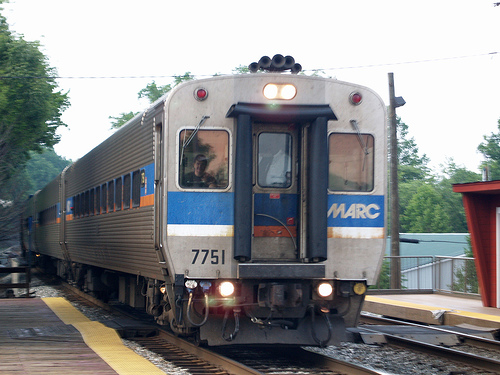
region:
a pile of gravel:
[348, 346, 420, 371]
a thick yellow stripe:
[43, 290, 148, 373]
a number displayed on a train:
[186, 245, 231, 271]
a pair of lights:
[260, 79, 305, 104]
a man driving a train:
[177, 153, 224, 193]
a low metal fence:
[385, 251, 484, 299]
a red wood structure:
[448, 170, 498, 310]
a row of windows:
[58, 178, 148, 215]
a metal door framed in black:
[233, 99, 338, 266]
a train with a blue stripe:
[1, 64, 401, 339]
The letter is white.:
[327, 198, 347, 223]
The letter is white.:
[342, 199, 357, 227]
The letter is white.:
[352, 199, 367, 221]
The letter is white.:
[364, 198, 384, 223]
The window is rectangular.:
[325, 128, 375, 191]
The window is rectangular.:
[172, 125, 228, 195]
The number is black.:
[185, 243, 202, 268]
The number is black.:
[198, 245, 211, 269]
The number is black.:
[208, 245, 220, 270]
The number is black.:
[218, 244, 228, 268]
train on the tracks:
[10, 48, 440, 364]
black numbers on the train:
[183, 242, 229, 268]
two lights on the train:
[216, 274, 336, 310]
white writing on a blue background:
[326, 197, 383, 224]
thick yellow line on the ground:
[41, 286, 168, 373]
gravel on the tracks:
[113, 316, 458, 373]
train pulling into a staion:
[1, 15, 498, 372]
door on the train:
[249, 119, 306, 266]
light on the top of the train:
[259, 82, 301, 100]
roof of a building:
[384, 224, 472, 276]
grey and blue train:
[35, 136, 397, 348]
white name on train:
[330, 183, 388, 230]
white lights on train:
[216, 273, 341, 305]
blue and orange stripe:
[32, 164, 177, 239]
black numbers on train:
[184, 239, 225, 279]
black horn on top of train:
[242, 43, 301, 77]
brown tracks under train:
[167, 342, 326, 374]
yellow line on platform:
[19, 282, 127, 374]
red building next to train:
[452, 154, 499, 282]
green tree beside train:
[0, 9, 92, 221]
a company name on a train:
[321, 195, 385, 227]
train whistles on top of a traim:
[243, 45, 311, 79]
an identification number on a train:
[186, 243, 233, 271]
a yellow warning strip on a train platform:
[40, 290, 162, 373]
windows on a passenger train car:
[57, 170, 159, 215]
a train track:
[162, 330, 251, 370]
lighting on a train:
[260, 76, 304, 104]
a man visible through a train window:
[259, 137, 301, 182]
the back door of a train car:
[225, 98, 335, 275]